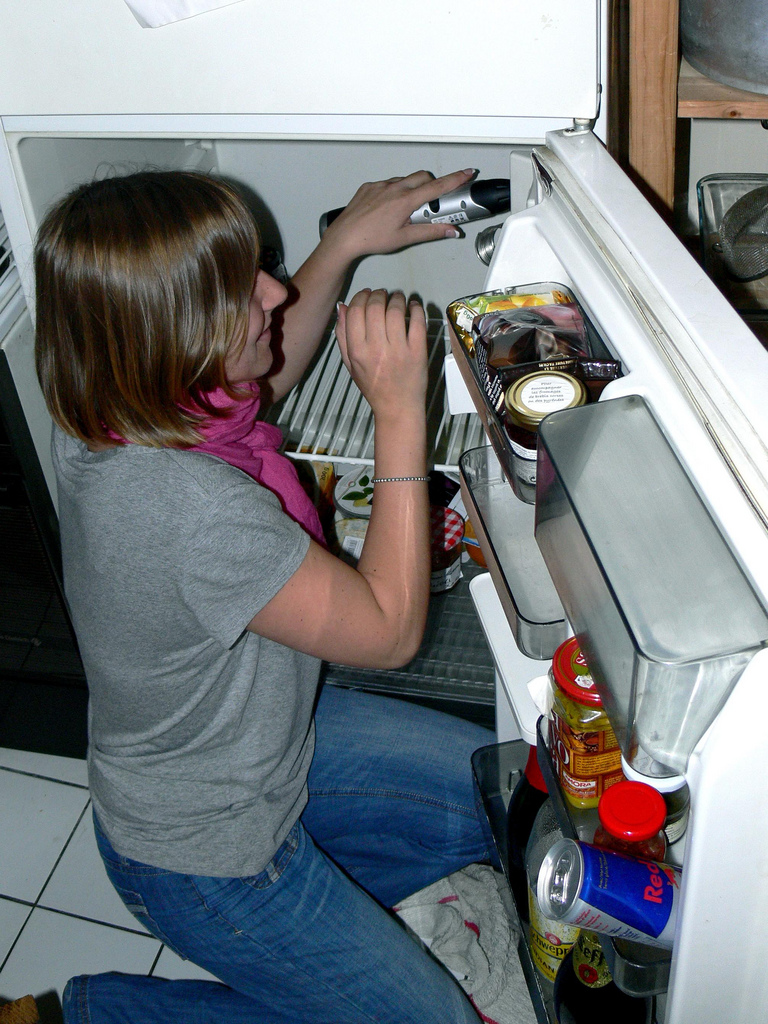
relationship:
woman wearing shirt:
[32, 178, 536, 1022] [32, 416, 351, 876]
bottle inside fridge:
[536, 838, 681, 951] [4, 4, 765, 1022]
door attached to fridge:
[466, 137, 763, 1022] [0, 0, 768, 1021]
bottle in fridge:
[548, 636, 630, 816] [0, 0, 768, 1021]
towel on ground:
[393, 862, 532, 1023] [6, 743, 540, 1022]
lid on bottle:
[597, 783, 666, 838] [597, 783, 673, 860]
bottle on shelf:
[530, 840, 686, 949] [467, 564, 684, 955]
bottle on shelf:
[596, 774, 670, 876] [467, 564, 684, 955]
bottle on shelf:
[545, 632, 622, 829] [463, 557, 678, 1001]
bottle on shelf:
[550, 918, 669, 1022] [471, 732, 669, 1022]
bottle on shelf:
[526, 795, 585, 983] [463, 735, 652, 1022]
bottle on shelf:
[548, 636, 630, 816] [476, 572, 705, 999]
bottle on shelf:
[464, 351, 595, 469] [416, 299, 705, 702]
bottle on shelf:
[330, 460, 384, 562] [294, 466, 520, 702]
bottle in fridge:
[526, 799, 585, 1005] [4, 4, 765, 1022]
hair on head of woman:
[34, 162, 256, 451] [19, 149, 471, 806]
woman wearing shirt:
[24, 155, 637, 1022] [40, 376, 372, 898]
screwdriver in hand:
[321, 171, 516, 249] [328, 164, 482, 262]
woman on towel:
[26, 165, 331, 552] [403, 887, 514, 990]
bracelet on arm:
[357, 465, 439, 489] [249, 266, 490, 673]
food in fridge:
[430, 506, 465, 594] [3, 2, 706, 705]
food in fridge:
[444, 283, 617, 482] [4, 4, 765, 1022]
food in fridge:
[273, 435, 377, 565] [4, 4, 765, 1022]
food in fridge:
[495, 635, 694, 1022] [4, 4, 765, 1022]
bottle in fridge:
[536, 838, 681, 951] [4, 4, 765, 1022]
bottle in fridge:
[505, 370, 587, 487] [4, 4, 765, 1022]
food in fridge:
[421, 498, 471, 601] [4, 4, 765, 1022]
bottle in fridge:
[548, 636, 630, 816] [4, 4, 765, 1022]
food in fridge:
[270, 430, 387, 534] [4, 4, 765, 1022]